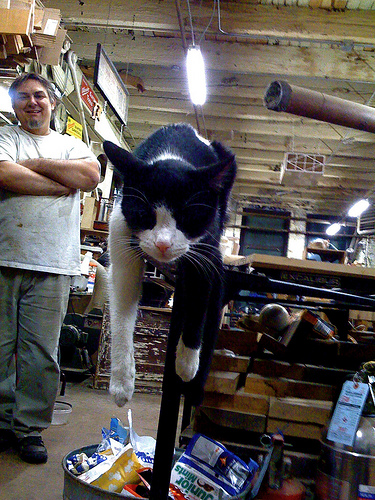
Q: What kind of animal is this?
A: Cat.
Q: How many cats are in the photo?
A: One.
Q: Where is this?
A: Workshop.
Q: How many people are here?
A: 1.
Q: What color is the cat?
A: Black and white.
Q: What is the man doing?
A: Watching the cat.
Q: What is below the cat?
A: Trash can.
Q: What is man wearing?
A: Tee shirt and dirty jeans.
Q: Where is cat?
A: Hanging off table.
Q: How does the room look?
A: Cluttered and messy.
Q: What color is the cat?
A: Black and white.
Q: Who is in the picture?
A: A man.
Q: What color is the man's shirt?
A: White.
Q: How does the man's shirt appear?
A: White.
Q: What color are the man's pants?
A: Grey.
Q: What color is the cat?
A: Black and white.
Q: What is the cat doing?
A: Sleeping.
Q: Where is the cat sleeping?
A: On a workbench.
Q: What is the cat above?
A: A trash bin.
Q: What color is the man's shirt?
A: White.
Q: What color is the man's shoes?
A: Black.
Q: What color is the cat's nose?
A: Pink.